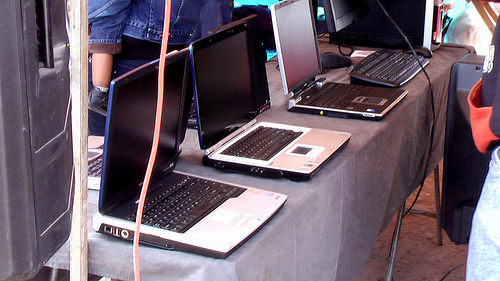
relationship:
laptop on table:
[89, 43, 292, 262] [40, 23, 478, 280]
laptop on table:
[184, 11, 356, 184] [40, 23, 478, 280]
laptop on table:
[265, 0, 414, 125] [40, 23, 478, 280]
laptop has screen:
[89, 43, 292, 262] [103, 54, 187, 207]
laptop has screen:
[184, 11, 356, 184] [192, 18, 271, 146]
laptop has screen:
[265, 0, 414, 125] [275, 0, 321, 92]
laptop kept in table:
[89, 43, 292, 262] [40, 23, 478, 280]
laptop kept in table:
[184, 11, 356, 184] [40, 23, 478, 280]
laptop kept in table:
[265, 0, 414, 125] [40, 23, 478, 280]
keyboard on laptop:
[122, 172, 249, 236] [89, 43, 292, 262]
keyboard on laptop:
[217, 122, 307, 163] [184, 11, 356, 184]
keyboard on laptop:
[305, 79, 376, 112] [265, 0, 414, 125]